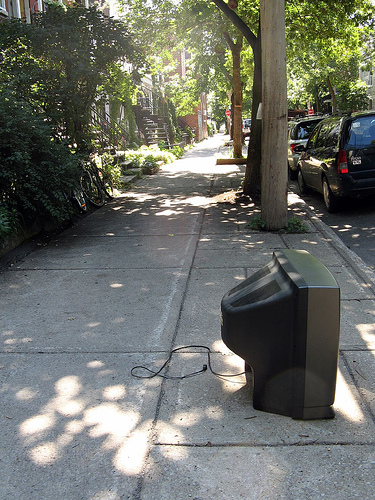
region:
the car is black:
[302, 129, 368, 198]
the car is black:
[347, 118, 357, 182]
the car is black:
[287, 141, 349, 179]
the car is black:
[291, 100, 352, 130]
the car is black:
[318, 131, 368, 247]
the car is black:
[299, 113, 344, 163]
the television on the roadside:
[136, 235, 352, 435]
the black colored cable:
[116, 330, 221, 406]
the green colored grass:
[286, 212, 309, 235]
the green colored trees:
[34, 8, 120, 185]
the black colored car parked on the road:
[303, 103, 373, 212]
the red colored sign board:
[220, 110, 233, 123]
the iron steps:
[136, 91, 181, 156]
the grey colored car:
[288, 115, 303, 168]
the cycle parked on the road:
[67, 149, 125, 213]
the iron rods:
[91, 107, 125, 158]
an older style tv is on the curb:
[133, 247, 339, 423]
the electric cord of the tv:
[129, 342, 249, 387]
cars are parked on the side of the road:
[240, 107, 373, 209]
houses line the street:
[5, 0, 213, 268]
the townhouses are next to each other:
[0, 0, 210, 188]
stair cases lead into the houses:
[54, 93, 181, 178]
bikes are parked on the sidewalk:
[62, 160, 117, 217]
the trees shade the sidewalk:
[59, 144, 374, 482]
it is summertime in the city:
[5, 1, 374, 250]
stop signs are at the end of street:
[222, 105, 317, 142]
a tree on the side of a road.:
[255, 0, 291, 225]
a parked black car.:
[287, 93, 373, 211]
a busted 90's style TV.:
[138, 240, 341, 418]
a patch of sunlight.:
[116, 411, 200, 486]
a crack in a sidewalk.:
[144, 429, 372, 458]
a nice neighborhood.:
[0, 2, 208, 278]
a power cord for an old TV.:
[126, 335, 243, 392]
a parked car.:
[291, 107, 374, 209]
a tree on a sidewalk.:
[213, 32, 251, 164]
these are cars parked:
[289, 108, 352, 193]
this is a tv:
[233, 246, 335, 424]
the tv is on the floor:
[226, 251, 343, 417]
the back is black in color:
[219, 275, 291, 367]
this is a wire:
[136, 333, 208, 393]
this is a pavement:
[62, 237, 182, 317]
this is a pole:
[261, 1, 286, 208]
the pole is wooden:
[265, 41, 281, 64]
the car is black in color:
[342, 152, 363, 184]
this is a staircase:
[149, 103, 163, 136]